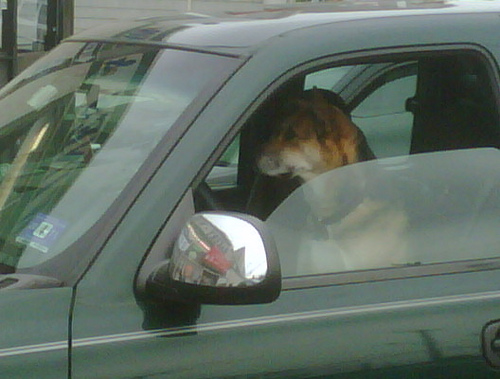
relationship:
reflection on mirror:
[188, 230, 237, 283] [157, 203, 275, 312]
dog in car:
[258, 94, 403, 257] [0, 8, 498, 378]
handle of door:
[483, 318, 499, 361] [71, 27, 499, 377]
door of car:
[71, 27, 499, 377] [0, 8, 498, 378]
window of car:
[265, 144, 498, 274] [0, 8, 498, 378]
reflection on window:
[285, 234, 340, 262] [265, 144, 498, 274]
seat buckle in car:
[397, 83, 438, 115] [0, 8, 498, 378]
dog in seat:
[258, 94, 403, 257] [410, 97, 497, 254]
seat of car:
[410, 97, 497, 254] [0, 8, 498, 378]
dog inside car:
[258, 94, 403, 257] [0, 8, 498, 378]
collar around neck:
[300, 175, 377, 237] [301, 135, 379, 226]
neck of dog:
[301, 135, 379, 226] [258, 94, 403, 257]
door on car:
[71, 27, 499, 377] [0, 8, 498, 378]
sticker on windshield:
[7, 206, 72, 259] [1, 43, 230, 272]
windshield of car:
[1, 43, 230, 272] [0, 8, 498, 378]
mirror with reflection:
[157, 203, 275, 312] [188, 230, 237, 283]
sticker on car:
[7, 206, 72, 259] [0, 8, 498, 378]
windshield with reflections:
[1, 43, 230, 272] [5, 52, 135, 205]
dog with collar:
[258, 94, 403, 257] [300, 175, 377, 237]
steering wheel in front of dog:
[194, 175, 238, 218] [258, 94, 403, 257]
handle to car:
[483, 318, 499, 361] [0, 8, 498, 378]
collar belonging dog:
[300, 175, 377, 237] [258, 94, 403, 257]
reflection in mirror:
[188, 230, 237, 283] [157, 203, 275, 312]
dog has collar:
[258, 94, 403, 257] [300, 175, 377, 237]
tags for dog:
[310, 222, 333, 241] [258, 94, 403, 257]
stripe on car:
[5, 289, 498, 372] [0, 8, 498, 378]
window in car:
[265, 144, 498, 274] [0, 8, 498, 378]